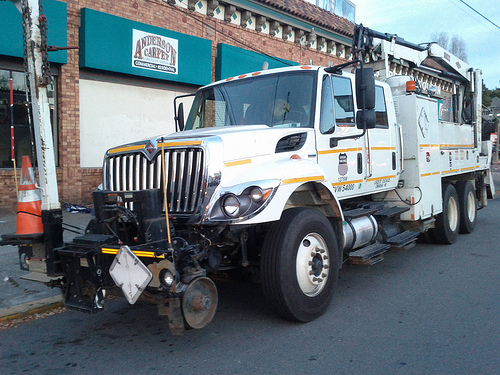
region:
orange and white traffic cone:
[5, 151, 37, 239]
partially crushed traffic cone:
[16, 155, 53, 246]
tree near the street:
[27, 2, 68, 278]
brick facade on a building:
[60, 17, 90, 189]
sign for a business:
[122, 34, 192, 80]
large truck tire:
[263, 227, 363, 330]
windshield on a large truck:
[185, 77, 312, 134]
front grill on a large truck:
[97, 139, 205, 213]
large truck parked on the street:
[45, 56, 492, 331]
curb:
[7, 301, 53, 322]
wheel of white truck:
[277, 227, 352, 279]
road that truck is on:
[351, 283, 426, 370]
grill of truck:
[122, 159, 209, 183]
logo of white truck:
[146, 140, 161, 160]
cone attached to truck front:
[13, 165, 48, 249]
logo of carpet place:
[118, 37, 185, 66]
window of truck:
[214, 94, 309, 120]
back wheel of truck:
[438, 170, 461, 252]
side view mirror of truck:
[352, 72, 389, 127]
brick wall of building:
[51, 90, 83, 160]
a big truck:
[63, 24, 493, 276]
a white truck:
[70, 41, 490, 295]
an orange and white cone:
[8, 144, 58, 261]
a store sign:
[64, 11, 231, 97]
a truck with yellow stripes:
[105, 101, 480, 234]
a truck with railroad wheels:
[19, 158, 436, 351]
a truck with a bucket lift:
[335, 29, 499, 151]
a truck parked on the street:
[53, 64, 490, 314]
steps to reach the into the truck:
[338, 181, 468, 273]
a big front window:
[185, 56, 382, 131]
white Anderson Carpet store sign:
[124, 23, 193, 79]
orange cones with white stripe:
[9, 153, 46, 244]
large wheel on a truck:
[257, 201, 352, 329]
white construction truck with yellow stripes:
[86, 21, 498, 296]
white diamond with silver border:
[103, 243, 162, 305]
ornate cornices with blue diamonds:
[199, 4, 348, 52]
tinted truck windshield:
[186, 78, 324, 124]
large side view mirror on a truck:
[341, 53, 393, 148]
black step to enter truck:
[351, 234, 431, 262]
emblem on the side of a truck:
[336, 148, 352, 198]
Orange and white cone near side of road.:
[14, 145, 106, 323]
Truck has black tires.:
[243, 199, 340, 339]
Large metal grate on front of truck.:
[86, 142, 233, 273]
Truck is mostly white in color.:
[178, 70, 358, 244]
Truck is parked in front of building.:
[83, 79, 365, 313]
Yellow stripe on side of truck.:
[228, 137, 486, 217]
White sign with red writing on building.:
[112, 46, 229, 97]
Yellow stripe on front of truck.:
[96, 140, 249, 171]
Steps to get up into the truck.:
[368, 172, 420, 287]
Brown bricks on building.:
[53, 80, 148, 240]